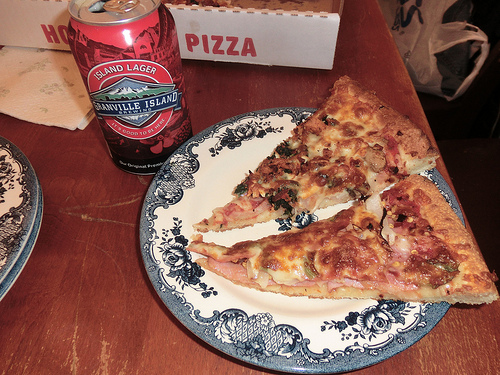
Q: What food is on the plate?
A: Pizza.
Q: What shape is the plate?
A: Round.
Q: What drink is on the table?
A: Island lager beer.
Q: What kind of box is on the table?
A: A pizza box.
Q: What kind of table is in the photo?
A: A wooden table.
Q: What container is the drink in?
A: A can.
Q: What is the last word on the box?
A: PIZZA.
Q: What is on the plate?
A: Two slices of pizza.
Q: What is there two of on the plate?
A: Pizza slices.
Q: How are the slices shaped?
A: Triangles.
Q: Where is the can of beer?
A: On table.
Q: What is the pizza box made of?
A: Cardboard.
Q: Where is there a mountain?
A: On beer label.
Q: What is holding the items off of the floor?
A: Table.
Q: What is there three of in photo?
A: Plates.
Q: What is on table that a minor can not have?
A: Beer.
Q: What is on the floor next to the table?
A: A plastic bag.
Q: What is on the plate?
A: Two pieces of pizza.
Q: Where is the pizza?
A: On the plate.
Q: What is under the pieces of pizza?
A: A plate.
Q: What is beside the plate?
A: A can of beer.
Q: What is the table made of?
A: Wood.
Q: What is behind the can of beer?
A: A pizza box.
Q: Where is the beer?
A: In a can by the plate with pizza.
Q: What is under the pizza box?
A: Wooden table.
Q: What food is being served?
A: Pizza.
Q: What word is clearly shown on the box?
A: Pizza.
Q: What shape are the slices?
A: Triangular.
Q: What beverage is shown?
A: Beer.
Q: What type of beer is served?
A: Lager.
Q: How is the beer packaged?
A: In cans.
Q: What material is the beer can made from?
A: Aluminum.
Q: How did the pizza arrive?
A: In a box.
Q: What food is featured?
A: Pizza.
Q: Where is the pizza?
A: On the plate.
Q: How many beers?
A: 1.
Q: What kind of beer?
A: Island Lager.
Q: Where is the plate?
A: On the table.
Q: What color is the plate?
A: White and blue.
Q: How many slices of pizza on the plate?
A: 2.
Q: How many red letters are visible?
A: 7.